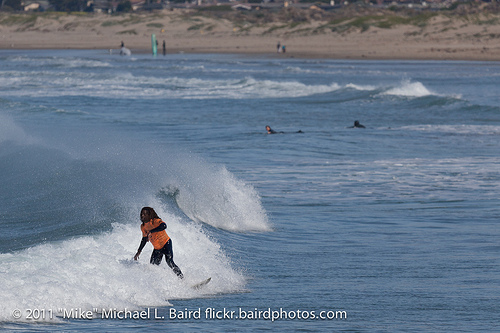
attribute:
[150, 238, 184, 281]
wet suit — Black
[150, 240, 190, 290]
pants — Black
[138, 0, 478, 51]
sandy hill — sandy 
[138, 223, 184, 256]
orange shirt — orange  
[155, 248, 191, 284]
black pants — black 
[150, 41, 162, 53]
green board — green 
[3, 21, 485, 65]
sandy beach — sandy 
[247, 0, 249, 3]
grass — green 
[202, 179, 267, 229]
wave — crashing , white top 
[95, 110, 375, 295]
surfer — male 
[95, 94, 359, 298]
surfer — male 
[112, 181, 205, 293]
surfer — male 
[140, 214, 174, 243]
top — orange 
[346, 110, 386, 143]
surfer — male 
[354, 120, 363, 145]
wetsuit — black 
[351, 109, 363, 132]
wetsuit — black 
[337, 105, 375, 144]
surfer — male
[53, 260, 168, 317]
waves — blue, white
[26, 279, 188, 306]
waves — blue , white  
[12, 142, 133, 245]
waves — white  , blue 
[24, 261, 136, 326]
waves — blue , white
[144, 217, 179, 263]
vest — Her life , orange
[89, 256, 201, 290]
surfboard — light blue 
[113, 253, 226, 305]
surfboard — dark 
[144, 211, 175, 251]
top — orange 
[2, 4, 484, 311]
photo — 2011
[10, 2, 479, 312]
picture — michael L Baird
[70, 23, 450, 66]
beach — Sandy 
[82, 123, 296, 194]
wave — White foamy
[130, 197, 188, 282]
man — surfing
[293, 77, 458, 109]
wave — rolling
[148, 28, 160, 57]
pole — green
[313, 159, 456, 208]
ripples — small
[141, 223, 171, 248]
top — orange